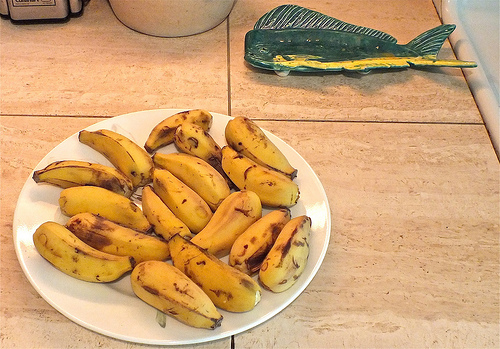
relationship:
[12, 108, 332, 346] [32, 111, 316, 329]
plate below bananas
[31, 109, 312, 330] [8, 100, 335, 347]
banana on plate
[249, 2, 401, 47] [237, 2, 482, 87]
fins on fish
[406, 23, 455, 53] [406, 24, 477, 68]
fins on fish tail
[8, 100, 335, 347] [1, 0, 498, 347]
plate on floor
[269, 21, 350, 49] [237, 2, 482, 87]
gills on fish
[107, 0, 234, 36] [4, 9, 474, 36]
pan on background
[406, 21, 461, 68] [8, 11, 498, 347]
fish tail on photo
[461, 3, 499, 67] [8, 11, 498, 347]
wall on photo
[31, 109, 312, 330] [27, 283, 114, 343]
banana on plate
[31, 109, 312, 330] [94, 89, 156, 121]
banana on plate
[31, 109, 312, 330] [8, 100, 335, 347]
banana on a plate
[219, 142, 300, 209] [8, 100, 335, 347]
banana on a plate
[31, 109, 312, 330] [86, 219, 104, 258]
banana with buising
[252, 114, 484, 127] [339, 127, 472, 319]
line separating tile